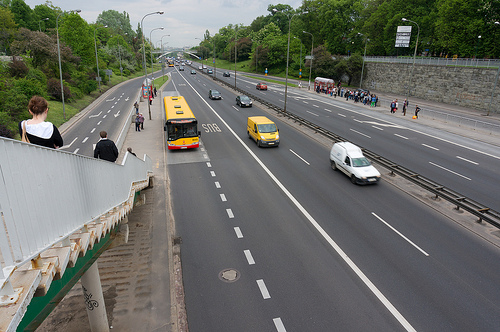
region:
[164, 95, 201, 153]
a yellow bus with a red bumper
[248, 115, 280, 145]
a yellow van with a black bumper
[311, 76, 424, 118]
a group of people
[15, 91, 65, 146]
a woman with short dark hair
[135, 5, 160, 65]
two overhead lights attached to poles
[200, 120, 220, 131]
the word "BUS" written in white on the road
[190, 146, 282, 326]
a broken white line painted on the road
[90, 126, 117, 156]
a man in black outerwear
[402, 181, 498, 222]
a small section of guardrail in the middle of the road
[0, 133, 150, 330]
a set of steps with a white rail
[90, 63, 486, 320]
lanes with several vehicles in them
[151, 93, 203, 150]
bus in one lane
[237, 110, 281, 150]
van in a lane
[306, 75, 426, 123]
group of people on side of street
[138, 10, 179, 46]
lights on the street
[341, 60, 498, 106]
wall on side of street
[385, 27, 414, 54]
banner above the wall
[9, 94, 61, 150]
female on the steps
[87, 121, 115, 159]
male on the steps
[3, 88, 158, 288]
a set of steps near road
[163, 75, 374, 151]
seven lanes of traffic on a highway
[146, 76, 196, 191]
a bus stopped at a curb to pick people up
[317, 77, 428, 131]
several people standing on the side of a road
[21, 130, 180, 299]
a long set of steps leading to a bus stop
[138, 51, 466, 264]
white lines painted on a highway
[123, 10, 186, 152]
several street lights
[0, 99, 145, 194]
three people walking down a stair way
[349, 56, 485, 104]
a tall rock wall next to a highway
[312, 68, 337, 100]
a red shelter at a bus stop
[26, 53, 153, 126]
a line of trees next to a highway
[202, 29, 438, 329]
vehicles driving down street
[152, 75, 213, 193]
bus on side of street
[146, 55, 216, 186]
bus is yellow with red trim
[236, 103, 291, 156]
yellow van driving on road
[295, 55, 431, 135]
group of people standing on side of road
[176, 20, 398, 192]
cars traveling in opposite directions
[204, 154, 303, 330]
white dashed line on road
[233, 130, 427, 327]
white solid line on road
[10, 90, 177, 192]
people walking down stairs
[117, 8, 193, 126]
street lights line roadway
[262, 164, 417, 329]
white solid line on the road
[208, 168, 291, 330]
white dotted line on the street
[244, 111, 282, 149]
yellow van on the road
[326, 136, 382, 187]
white car on the street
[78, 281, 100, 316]
black graffiti on the pole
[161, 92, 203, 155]
yellow, black and red bus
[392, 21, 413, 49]
white and black sign above the wall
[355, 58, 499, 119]
gray wall next to the street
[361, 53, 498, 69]
white fence on top of the wall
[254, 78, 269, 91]
red car on the street